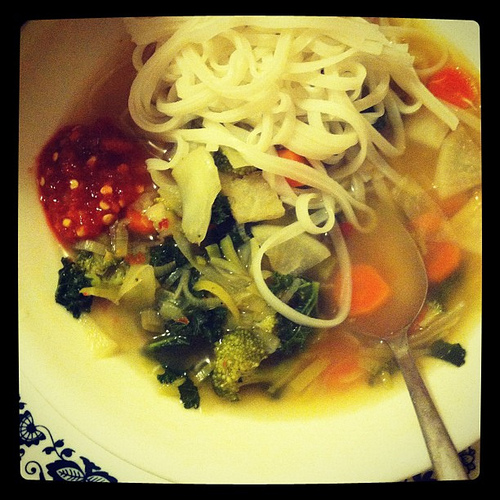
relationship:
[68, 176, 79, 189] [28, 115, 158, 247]
seed in sauce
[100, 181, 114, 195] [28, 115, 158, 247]
seed in sauce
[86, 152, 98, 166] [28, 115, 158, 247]
seed in sauce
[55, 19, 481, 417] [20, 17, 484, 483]
vegetable soup in bowl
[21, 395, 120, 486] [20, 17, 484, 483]
design on bowl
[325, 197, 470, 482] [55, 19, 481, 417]
spoon in vegetable soup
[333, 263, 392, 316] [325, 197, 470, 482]
carrot on spoon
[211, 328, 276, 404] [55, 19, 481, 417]
broccoli in vegetable soup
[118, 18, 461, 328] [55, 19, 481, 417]
noodles on top of vegetable soup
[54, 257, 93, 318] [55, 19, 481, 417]
kale in vegetable soup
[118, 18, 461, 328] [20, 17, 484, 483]
noodles in bowl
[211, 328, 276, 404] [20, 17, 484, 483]
broccoli in bowl